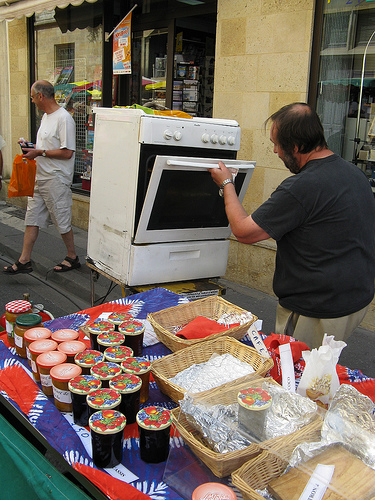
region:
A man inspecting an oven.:
[79, 75, 368, 345]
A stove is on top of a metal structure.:
[75, 91, 247, 292]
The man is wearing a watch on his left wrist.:
[202, 151, 240, 199]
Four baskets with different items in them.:
[157, 286, 367, 493]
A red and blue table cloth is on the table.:
[0, 280, 369, 492]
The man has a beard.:
[261, 100, 327, 177]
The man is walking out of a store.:
[3, 70, 82, 280]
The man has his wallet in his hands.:
[1, 63, 83, 277]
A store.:
[39, 0, 249, 108]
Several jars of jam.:
[6, 286, 172, 474]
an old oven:
[83, 107, 253, 289]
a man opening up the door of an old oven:
[207, 99, 374, 351]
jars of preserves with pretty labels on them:
[70, 310, 174, 471]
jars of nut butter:
[25, 322, 82, 410]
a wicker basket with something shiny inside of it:
[151, 334, 274, 400]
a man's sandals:
[4, 255, 86, 279]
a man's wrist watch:
[214, 176, 239, 196]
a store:
[34, 11, 218, 180]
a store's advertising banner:
[107, 4, 137, 77]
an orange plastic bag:
[6, 153, 39, 199]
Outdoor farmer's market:
[8, 87, 371, 482]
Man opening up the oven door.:
[75, 86, 369, 300]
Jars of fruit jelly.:
[3, 301, 159, 451]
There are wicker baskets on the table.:
[136, 292, 334, 494]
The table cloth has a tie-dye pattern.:
[0, 285, 360, 489]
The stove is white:
[93, 100, 247, 288]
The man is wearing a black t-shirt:
[240, 110, 374, 315]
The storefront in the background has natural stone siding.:
[217, 9, 309, 96]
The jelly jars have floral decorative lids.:
[91, 349, 185, 448]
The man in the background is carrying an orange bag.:
[3, 66, 79, 285]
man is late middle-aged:
[0, 78, 80, 279]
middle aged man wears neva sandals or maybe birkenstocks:
[1, 252, 81, 278]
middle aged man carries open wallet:
[14, 135, 38, 159]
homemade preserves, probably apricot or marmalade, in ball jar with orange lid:
[48, 361, 83, 414]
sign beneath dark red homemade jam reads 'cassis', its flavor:
[104, 463, 137, 482]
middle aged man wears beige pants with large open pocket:
[281, 306, 303, 336]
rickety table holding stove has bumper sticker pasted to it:
[173, 287, 220, 302]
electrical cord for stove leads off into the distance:
[0, 252, 121, 310]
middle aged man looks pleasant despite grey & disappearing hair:
[28, 78, 64, 115]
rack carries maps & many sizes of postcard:
[173, 61, 200, 116]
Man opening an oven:
[192, 92, 370, 369]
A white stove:
[77, 95, 254, 291]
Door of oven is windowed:
[130, 148, 257, 249]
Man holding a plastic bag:
[7, 76, 85, 286]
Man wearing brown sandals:
[3, 81, 86, 284]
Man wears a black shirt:
[204, 96, 373, 368]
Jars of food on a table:
[5, 283, 373, 498]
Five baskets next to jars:
[145, 291, 372, 498]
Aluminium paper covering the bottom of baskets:
[141, 289, 373, 499]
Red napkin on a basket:
[171, 302, 243, 342]